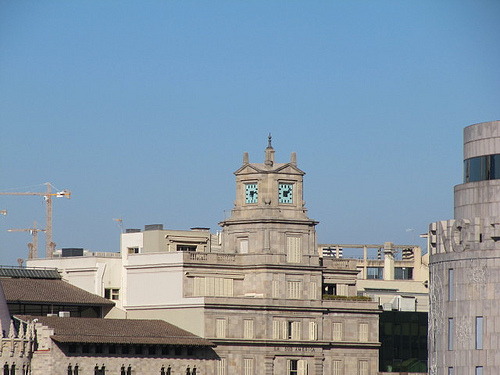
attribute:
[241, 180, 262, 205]
clock — blue, old, square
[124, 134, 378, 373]
building — old, tall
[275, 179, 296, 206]
clock — blue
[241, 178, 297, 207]
clocks — blue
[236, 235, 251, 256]
window — square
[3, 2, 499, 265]
sky — blue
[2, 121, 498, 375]
buildings — grey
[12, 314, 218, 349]
roof — brown